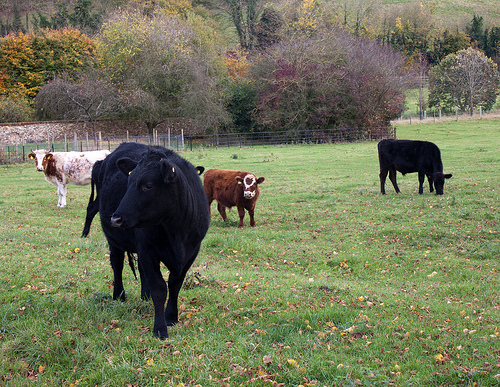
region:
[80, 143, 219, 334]
black furry large cow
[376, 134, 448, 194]
black furry large cow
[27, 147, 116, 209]
brown and white cow with horns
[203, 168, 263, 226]
brown and white cow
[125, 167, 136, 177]
yellow plastic identifier tag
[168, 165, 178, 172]
yellow plastic identifier tag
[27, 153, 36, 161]
yellow plastic identifier tag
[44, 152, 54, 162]
yellow plastic identifier tag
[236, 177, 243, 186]
yellow plastic identifier tag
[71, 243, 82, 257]
yellow fallen dry leaf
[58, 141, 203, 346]
a black cow with its head turned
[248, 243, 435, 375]
several leaves on the ground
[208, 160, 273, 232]
a brown cow with a white face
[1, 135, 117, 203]
a white cow with brown spots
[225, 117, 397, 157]
a wooden fence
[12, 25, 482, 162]
several trees along a fence line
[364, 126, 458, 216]
a black cow leaning down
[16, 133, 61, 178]
a cow with horns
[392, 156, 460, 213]
a cow eating grass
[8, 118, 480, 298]
four cows in a field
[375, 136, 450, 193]
Solid black cow grazing in a field.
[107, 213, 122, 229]
Nose of a solid black cow.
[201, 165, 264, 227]
Brown and white cow standing in the middle of other cows.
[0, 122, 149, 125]
Thin piece of train tracks up on a gravel hill.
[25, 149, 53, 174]
Brown and white face of a cow with a yellow tag in each ear.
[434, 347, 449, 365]
Leaves laying in the green grass.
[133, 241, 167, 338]
Front right leg of a solid black cow.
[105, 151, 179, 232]
Head of a solid black cow.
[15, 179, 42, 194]
Green grass by a white and brown cow.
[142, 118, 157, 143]
Tree trunk in the distance.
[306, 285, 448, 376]
the grass is green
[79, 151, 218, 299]
the cow is black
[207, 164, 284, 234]
the cow is brown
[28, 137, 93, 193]
the cow is white with spots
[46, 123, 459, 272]
there are four cows in the picture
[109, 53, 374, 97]
there are trees in the background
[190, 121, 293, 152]
there is fence around the field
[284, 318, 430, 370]
there are dry leaves on the filed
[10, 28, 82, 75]
the trees are colorful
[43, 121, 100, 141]
the walls are made of stone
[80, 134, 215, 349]
black cow in the foreground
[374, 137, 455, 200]
black cow in the background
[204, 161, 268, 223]
The small brown cow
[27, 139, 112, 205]
The white and brown cow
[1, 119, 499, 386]
The grass field the cows are in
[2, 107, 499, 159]
Fence behind the cows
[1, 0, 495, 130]
The trees in the background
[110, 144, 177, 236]
The head of the closest black cow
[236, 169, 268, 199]
The head of the brown cow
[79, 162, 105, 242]
The tail of the closest black cow